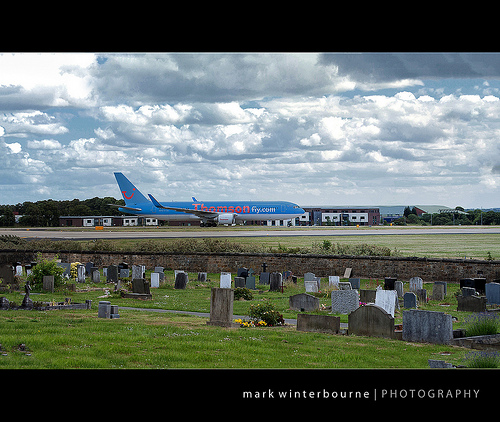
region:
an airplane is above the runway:
[57, 167, 305, 228]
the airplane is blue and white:
[55, 166, 306, 226]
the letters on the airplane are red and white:
[191, 199, 278, 214]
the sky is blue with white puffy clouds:
[0, 55, 499, 216]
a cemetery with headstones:
[0, 257, 499, 364]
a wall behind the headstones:
[2, 246, 497, 286]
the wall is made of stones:
[2, 245, 497, 287]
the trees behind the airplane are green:
[0, 190, 127, 219]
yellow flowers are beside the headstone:
[234, 314, 269, 331]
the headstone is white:
[217, 265, 233, 287]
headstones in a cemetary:
[0, 264, 498, 366]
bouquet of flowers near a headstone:
[236, 303, 288, 328]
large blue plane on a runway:
[111, 170, 305, 227]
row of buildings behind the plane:
[59, 206, 381, 225]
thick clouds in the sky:
[0, 53, 498, 203]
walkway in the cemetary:
[4, 306, 499, 331]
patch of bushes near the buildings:
[380, 207, 498, 226]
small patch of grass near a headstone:
[466, 316, 496, 333]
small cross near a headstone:
[277, 279, 287, 293]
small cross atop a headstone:
[260, 262, 268, 274]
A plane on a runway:
[57, 171, 305, 228]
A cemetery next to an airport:
[5, 146, 493, 352]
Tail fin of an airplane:
[113, 170, 148, 203]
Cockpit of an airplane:
[284, 200, 305, 224]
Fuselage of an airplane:
[148, 197, 279, 222]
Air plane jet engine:
[211, 210, 236, 225]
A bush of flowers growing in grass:
[236, 297, 286, 334]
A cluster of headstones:
[17, 252, 194, 300]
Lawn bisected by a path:
[156, 291, 206, 333]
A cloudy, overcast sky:
[161, 94, 491, 194]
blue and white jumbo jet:
[110, 171, 307, 229]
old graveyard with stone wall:
[2, 244, 491, 349]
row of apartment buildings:
[305, 208, 377, 225]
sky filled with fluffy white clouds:
[7, 56, 488, 168]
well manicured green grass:
[32, 333, 352, 368]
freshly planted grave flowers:
[231, 312, 273, 328]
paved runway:
[30, 222, 486, 239]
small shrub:
[14, 258, 66, 308]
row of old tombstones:
[208, 285, 461, 343]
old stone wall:
[162, 251, 317, 276]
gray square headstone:
[401, 305, 458, 343]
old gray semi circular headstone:
[346, 303, 403, 345]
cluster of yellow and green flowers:
[237, 301, 287, 330]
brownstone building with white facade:
[318, 202, 383, 229]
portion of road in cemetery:
[123, 301, 206, 327]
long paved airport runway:
[0, 221, 493, 245]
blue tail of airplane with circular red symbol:
[107, 167, 149, 227]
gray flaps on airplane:
[145, 188, 229, 220]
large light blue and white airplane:
[100, 158, 328, 231]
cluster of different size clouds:
[8, 61, 483, 178]